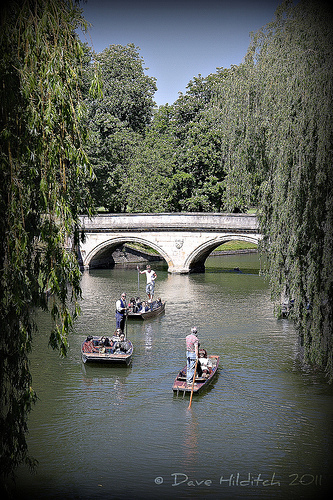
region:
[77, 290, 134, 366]
man is standing in boat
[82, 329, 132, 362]
people are sitting in boat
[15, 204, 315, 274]
bridge is in the water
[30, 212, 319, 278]
bridge is in the picture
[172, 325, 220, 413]
person is standing on boat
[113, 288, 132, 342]
man in the picture is looking toward camera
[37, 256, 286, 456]
boats are on the water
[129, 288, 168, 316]
people are sitting in the boat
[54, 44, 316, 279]
green trees are behind the bridge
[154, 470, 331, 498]
letters are the color white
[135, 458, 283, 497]
Grey lettering at bottom of photo.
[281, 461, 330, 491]
A date the photo was taken bottom right of photo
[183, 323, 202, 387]
Man stands alone on boat.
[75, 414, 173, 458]
Beautiful green ocean water.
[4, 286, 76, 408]
Trees hang down over water.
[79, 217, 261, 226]
White greyish bridge in front of boats.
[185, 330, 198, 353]
Man wears a bluish pinkish shirt.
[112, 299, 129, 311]
Man wears a white shirt with blue vest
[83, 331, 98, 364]
Lady sits down in boat.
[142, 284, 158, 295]
Man wears blue jean shorts.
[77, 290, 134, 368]
people are in boat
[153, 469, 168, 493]
sign stands for copyright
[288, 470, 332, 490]
year is in the photo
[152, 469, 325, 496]
letters are in the color white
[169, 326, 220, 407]
person is standing on boats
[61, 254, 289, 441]
boats are traveling on water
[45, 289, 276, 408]
water has boats on it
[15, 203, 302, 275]
bridge is made of stone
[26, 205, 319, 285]
stone bridge is on water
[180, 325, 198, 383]
man standing in boat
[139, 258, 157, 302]
man standing in boat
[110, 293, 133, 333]
man standing in boat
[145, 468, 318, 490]
copyright of photo in corner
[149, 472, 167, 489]
copyright symbol on photo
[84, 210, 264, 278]
grey cement bridge with arches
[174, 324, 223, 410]
boat in water with people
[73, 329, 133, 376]
boat in water with people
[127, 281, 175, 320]
boat in water with people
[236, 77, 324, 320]
tree with hanging branches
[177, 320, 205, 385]
A man in jeans on a boat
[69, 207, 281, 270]
A stone bridge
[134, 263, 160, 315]
Man holding a pole on a boat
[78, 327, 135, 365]
Group of people on a boat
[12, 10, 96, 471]
Green leaves of a tree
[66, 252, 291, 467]
A river with people on it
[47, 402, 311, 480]
Murky river water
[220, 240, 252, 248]
A grass lawn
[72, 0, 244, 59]
Blue sky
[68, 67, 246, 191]
A group of trees